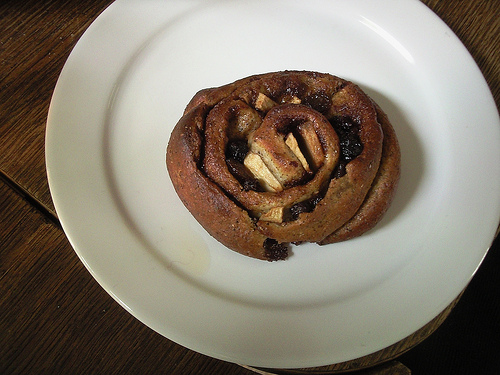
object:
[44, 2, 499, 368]
plate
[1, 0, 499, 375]
table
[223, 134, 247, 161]
raisin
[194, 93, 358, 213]
swirls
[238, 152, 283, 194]
apple chunk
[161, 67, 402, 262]
roll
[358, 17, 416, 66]
light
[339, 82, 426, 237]
shadow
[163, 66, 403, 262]
cinnamon bun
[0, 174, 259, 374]
section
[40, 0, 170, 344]
left side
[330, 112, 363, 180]
filling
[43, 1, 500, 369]
section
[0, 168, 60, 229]
seam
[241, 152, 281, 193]
filling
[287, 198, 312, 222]
raisins